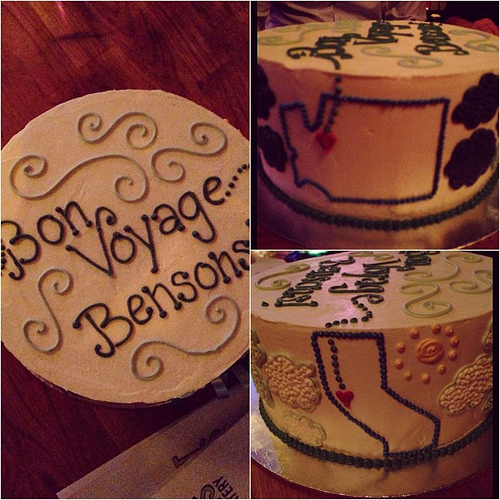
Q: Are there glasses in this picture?
A: No, there are no glasses.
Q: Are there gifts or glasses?
A: No, there are no glasses or gifts.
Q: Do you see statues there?
A: No, there are no statues.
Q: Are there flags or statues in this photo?
A: No, there are no statues or flags.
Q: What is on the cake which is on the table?
A: The letter is on the cake.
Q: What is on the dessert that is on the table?
A: The letter is on the cake.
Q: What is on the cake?
A: The letter is on the cake.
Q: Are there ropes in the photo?
A: No, there are no ropes.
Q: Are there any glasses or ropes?
A: No, there are no ropes or glasses.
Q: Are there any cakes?
A: Yes, there is a cake.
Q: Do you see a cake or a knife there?
A: Yes, there is a cake.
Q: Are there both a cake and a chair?
A: No, there is a cake but no chairs.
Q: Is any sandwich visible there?
A: No, there are no sandwiches.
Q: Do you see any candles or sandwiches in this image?
A: No, there are no sandwiches or candles.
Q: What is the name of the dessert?
A: The dessert is a cake.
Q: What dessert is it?
A: The dessert is a cake.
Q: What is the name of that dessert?
A: This is a cake.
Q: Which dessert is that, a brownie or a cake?
A: This is a cake.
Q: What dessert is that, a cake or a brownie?
A: This is a cake.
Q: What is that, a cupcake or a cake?
A: That is a cake.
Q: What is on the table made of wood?
A: The cake is on the table.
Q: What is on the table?
A: The cake is on the table.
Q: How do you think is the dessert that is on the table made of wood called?
A: The dessert is a cake.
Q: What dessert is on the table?
A: The dessert is a cake.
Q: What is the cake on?
A: The cake is on the table.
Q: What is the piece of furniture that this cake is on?
A: The piece of furniture is a table.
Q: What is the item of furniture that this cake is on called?
A: The piece of furniture is a table.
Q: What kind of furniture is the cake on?
A: The cake is on the table.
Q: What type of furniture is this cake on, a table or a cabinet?
A: The cake is on a table.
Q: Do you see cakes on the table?
A: Yes, there is a cake on the table.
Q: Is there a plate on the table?
A: No, there is a cake on the table.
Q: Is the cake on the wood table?
A: Yes, the cake is on the table.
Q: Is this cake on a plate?
A: No, the cake is on the table.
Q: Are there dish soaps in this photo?
A: No, there are no dish soaps.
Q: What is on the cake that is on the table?
A: The letter is on the cake.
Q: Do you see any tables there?
A: Yes, there is a table.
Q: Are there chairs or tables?
A: Yes, there is a table.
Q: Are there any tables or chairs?
A: Yes, there is a table.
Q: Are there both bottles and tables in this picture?
A: No, there is a table but no bottles.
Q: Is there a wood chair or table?
A: Yes, there is a wood table.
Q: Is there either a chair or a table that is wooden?
A: Yes, the table is wooden.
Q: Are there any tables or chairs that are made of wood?
A: Yes, the table is made of wood.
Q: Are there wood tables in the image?
A: Yes, there is a wood table.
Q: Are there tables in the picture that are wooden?
A: Yes, there is a table that is wooden.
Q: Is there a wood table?
A: Yes, there is a table that is made of wood.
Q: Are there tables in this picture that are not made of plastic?
A: Yes, there is a table that is made of wood.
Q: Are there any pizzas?
A: No, there are no pizzas.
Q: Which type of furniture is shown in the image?
A: The furniture is a table.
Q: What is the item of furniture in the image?
A: The piece of furniture is a table.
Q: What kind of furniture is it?
A: The piece of furniture is a table.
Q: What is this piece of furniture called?
A: This is a table.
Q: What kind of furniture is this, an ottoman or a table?
A: This is a table.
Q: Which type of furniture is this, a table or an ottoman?
A: This is a table.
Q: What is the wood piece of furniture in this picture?
A: The piece of furniture is a table.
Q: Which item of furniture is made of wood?
A: The piece of furniture is a table.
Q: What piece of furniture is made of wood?
A: The piece of furniture is a table.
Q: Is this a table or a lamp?
A: This is a table.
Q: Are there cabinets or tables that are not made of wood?
A: No, there is a table but it is made of wood.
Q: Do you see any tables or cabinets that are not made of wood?
A: No, there is a table but it is made of wood.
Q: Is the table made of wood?
A: Yes, the table is made of wood.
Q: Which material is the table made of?
A: The table is made of wood.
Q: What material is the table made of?
A: The table is made of wood.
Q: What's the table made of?
A: The table is made of wood.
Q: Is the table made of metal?
A: No, the table is made of wood.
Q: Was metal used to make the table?
A: No, the table is made of wood.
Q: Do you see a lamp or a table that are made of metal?
A: No, there is a table but it is made of wood.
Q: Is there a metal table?
A: No, there is a table but it is made of wood.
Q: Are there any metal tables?
A: No, there is a table but it is made of wood.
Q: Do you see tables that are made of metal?
A: No, there is a table but it is made of wood.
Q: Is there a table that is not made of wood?
A: No, there is a table but it is made of wood.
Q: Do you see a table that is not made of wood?
A: No, there is a table but it is made of wood.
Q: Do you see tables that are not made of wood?
A: No, there is a table but it is made of wood.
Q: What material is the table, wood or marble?
A: The table is made of wood.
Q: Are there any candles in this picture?
A: No, there are no candles.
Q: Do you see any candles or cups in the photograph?
A: No, there are no candles or cups.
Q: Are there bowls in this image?
A: No, there are no bowls.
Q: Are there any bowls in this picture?
A: No, there are no bowls.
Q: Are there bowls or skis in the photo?
A: No, there are no bowls or skis.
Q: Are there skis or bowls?
A: No, there are no bowls or skis.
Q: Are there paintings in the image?
A: No, there are no paintings.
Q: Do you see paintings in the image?
A: No, there are no paintings.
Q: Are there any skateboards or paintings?
A: No, there are no paintings or skateboards.